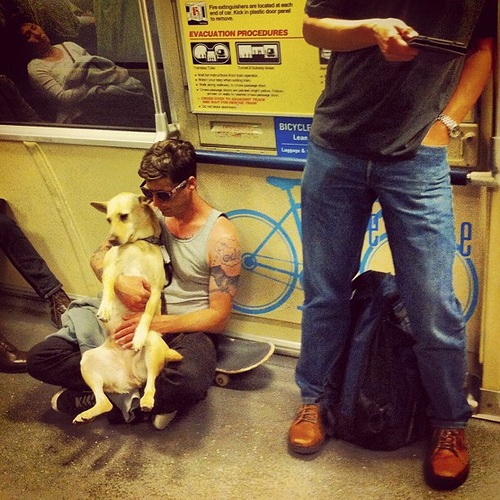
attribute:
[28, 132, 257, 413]
man — sitting, young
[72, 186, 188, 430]
dog — white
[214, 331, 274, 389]
skateboard — black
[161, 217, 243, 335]
arm — man's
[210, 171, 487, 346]
bicycle — blue, image, turquoise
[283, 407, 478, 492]
boots — brown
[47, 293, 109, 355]
coat — blue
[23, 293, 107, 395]
leg — man's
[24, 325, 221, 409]
jeans — denim, skinny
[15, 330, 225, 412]
legs — man's, crossed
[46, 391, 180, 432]
shoes — black, white, laced, reddish brown, dark brow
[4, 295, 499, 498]
floor — black, solid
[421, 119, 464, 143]
hand — man's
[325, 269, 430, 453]
backpack — navy, man's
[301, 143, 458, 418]
legs — man's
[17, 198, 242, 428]
body — man's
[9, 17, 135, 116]
reflection — woman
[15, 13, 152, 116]
woman — leaning, sleping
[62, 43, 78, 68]
strap — dark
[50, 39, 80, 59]
shoulder — woman's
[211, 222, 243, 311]
upper arm — man's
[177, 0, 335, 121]
board — yellow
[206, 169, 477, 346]
painting — bicycle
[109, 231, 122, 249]
nose — dark brown, dog's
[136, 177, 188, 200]
sunglasses — dark, plastic, pair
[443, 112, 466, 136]
wristwatch — silver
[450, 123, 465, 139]
face — dark, clock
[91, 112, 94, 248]
pants — black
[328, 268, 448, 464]
bag — black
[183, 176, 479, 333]
bike — blue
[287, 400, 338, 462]
shoe — brown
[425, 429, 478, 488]
shoe — brown, man's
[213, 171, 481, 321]
picture — bicycle, drawn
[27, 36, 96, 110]
shirt — white